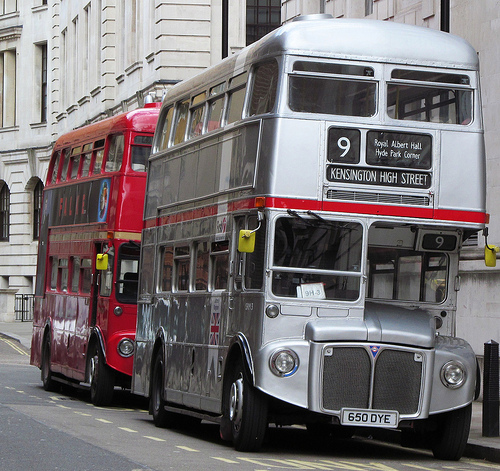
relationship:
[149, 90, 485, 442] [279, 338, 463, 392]
bus has headlamps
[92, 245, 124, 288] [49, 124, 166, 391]
mirror on bus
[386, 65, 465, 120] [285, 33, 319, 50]
window on 2nd level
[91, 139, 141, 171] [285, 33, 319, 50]
window on 2nd level